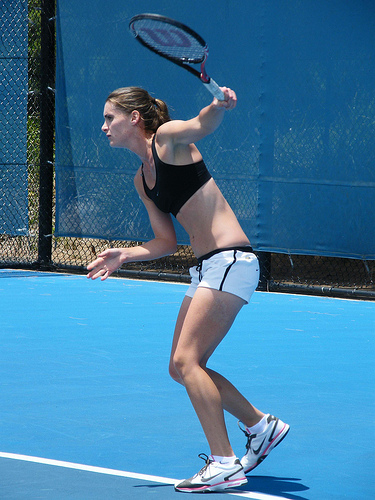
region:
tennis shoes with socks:
[171, 409, 312, 498]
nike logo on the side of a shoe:
[195, 471, 226, 484]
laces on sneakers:
[194, 449, 210, 477]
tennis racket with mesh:
[117, 7, 226, 92]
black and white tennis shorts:
[184, 234, 261, 328]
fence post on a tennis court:
[25, 41, 79, 398]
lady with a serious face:
[92, 82, 162, 165]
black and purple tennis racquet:
[129, 13, 226, 101]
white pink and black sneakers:
[176, 416, 288, 494]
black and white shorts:
[182, 245, 260, 303]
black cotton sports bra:
[131, 129, 211, 219]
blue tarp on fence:
[54, 1, 372, 261]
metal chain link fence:
[56, 1, 372, 295]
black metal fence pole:
[38, 1, 53, 268]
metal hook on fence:
[47, 159, 52, 167]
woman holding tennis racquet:
[86, 14, 289, 487]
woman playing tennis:
[87, 14, 289, 491]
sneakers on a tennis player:
[166, 403, 291, 490]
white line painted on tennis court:
[7, 445, 131, 482]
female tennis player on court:
[60, 5, 290, 491]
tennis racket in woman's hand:
[120, 2, 249, 103]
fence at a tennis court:
[1, 7, 76, 270]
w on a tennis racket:
[138, 21, 190, 51]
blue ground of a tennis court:
[276, 302, 356, 418]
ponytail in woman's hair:
[142, 93, 175, 122]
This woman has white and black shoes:
[202, 460, 217, 497]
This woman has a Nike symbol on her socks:
[216, 448, 229, 478]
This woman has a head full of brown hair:
[121, 98, 140, 132]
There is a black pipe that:
[27, 100, 59, 196]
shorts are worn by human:
[183, 245, 259, 301]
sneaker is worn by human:
[238, 408, 289, 478]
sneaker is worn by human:
[169, 452, 248, 495]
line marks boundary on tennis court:
[1, 448, 294, 498]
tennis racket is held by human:
[127, 12, 227, 103]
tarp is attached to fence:
[49, 0, 373, 261]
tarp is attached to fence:
[0, 0, 32, 240]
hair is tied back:
[109, 86, 169, 131]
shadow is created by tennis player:
[132, 468, 308, 498]